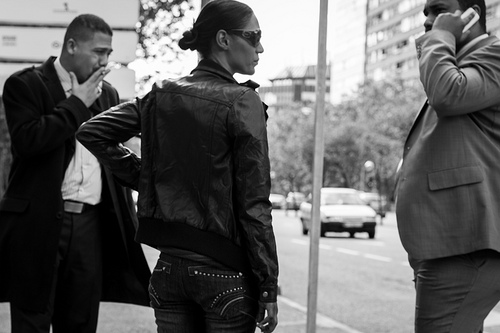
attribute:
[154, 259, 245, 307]
studs — metal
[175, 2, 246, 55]
hair — bun style, up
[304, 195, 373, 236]
car — white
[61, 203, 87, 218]
belt clip — metal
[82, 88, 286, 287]
jacket — leather, dark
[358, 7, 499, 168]
building — tall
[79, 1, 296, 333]
woman — standing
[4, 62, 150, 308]
coat — black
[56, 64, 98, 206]
shirt — white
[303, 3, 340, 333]
pole — metal